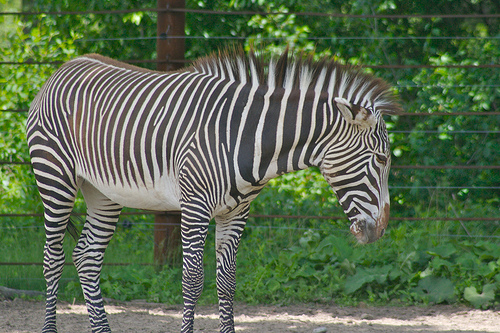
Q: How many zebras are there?
A: One.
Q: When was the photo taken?
A: Daytime.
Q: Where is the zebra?
A: In a zoo.